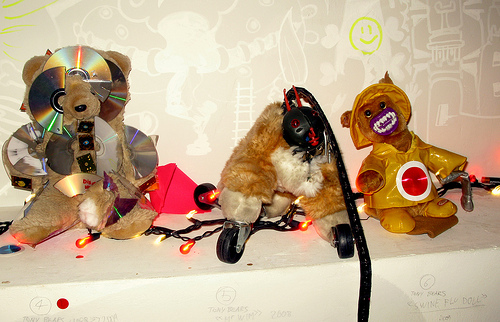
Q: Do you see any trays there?
A: No, there are no trays.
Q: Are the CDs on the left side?
A: Yes, the CDs are on the left of the image.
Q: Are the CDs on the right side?
A: No, the CDs are on the left of the image.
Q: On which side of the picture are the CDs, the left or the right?
A: The CDs are on the left of the image.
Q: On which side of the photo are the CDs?
A: The CDs are on the left of the image.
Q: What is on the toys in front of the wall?
A: The CDs are on the toys.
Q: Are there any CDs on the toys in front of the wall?
A: Yes, there are CDs on the toys.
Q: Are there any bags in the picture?
A: No, there are no bags.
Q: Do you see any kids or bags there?
A: No, there are no bags or kids.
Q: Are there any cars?
A: No, there are no cars.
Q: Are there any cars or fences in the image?
A: No, there are no cars or fences.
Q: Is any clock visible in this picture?
A: No, there are no clocks.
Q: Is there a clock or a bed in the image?
A: No, there are no clocks or beds.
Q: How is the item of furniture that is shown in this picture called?
A: The piece of furniture is a shelf.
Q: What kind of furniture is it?
A: The piece of furniture is a shelf.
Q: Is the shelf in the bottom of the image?
A: Yes, the shelf is in the bottom of the image.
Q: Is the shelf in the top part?
A: No, the shelf is in the bottom of the image.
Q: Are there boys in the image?
A: No, there are no boys.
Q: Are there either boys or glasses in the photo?
A: No, there are no boys or glasses.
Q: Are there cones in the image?
A: No, there are no cones.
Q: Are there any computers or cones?
A: No, there are no cones or computers.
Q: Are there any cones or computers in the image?
A: No, there are no cones or computers.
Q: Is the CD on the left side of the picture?
A: Yes, the CD is on the left of the image.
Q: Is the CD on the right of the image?
A: No, the CD is on the left of the image.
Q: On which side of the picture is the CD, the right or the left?
A: The CD is on the left of the image.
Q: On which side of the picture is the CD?
A: The CD is on the left of the image.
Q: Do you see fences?
A: No, there are no fences.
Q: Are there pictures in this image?
A: No, there are no pictures.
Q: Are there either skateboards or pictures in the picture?
A: No, there are no pictures or skateboards.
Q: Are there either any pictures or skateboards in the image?
A: No, there are no pictures or skateboards.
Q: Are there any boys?
A: No, there are no boys.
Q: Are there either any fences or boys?
A: No, there are no boys or fences.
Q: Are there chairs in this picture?
A: No, there are no chairs.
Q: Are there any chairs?
A: No, there are no chairs.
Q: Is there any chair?
A: No, there are no chairs.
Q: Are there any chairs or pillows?
A: No, there are no chairs or pillows.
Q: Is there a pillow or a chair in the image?
A: No, there are no chairs or pillows.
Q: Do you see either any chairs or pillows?
A: No, there are no chairs or pillows.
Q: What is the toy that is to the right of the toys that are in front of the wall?
A: The toy is a stuffed animal.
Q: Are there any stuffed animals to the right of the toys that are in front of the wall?
A: Yes, there is a stuffed animal to the right of the toys.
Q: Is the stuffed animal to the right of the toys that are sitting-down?
A: Yes, the stuffed animal is to the right of the toys.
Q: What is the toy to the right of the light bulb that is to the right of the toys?
A: The toy is a stuffed animal.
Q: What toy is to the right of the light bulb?
A: The toy is a stuffed animal.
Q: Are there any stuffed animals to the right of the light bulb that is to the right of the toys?
A: Yes, there is a stuffed animal to the right of the bulb.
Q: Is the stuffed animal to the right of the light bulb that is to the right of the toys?
A: Yes, the stuffed animal is to the right of the bulb.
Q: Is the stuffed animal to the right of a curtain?
A: No, the stuffed animal is to the right of the bulb.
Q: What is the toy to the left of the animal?
A: The toy is a stuffed animal.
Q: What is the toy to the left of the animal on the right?
A: The toy is a stuffed animal.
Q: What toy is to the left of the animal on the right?
A: The toy is a stuffed animal.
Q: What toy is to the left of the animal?
A: The toy is a stuffed animal.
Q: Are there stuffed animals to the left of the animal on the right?
A: Yes, there is a stuffed animal to the left of the animal.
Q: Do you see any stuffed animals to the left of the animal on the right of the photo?
A: Yes, there is a stuffed animal to the left of the animal.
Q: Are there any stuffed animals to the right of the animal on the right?
A: No, the stuffed animal is to the left of the animal.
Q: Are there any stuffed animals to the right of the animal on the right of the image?
A: No, the stuffed animal is to the left of the animal.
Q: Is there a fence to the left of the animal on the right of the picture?
A: No, there is a stuffed animal to the left of the animal.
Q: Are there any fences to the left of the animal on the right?
A: No, there is a stuffed animal to the left of the animal.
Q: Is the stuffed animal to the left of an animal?
A: Yes, the stuffed animal is to the left of an animal.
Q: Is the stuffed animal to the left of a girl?
A: No, the stuffed animal is to the left of an animal.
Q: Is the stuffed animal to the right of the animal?
A: No, the stuffed animal is to the left of the animal.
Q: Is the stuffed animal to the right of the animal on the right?
A: No, the stuffed animal is to the left of the animal.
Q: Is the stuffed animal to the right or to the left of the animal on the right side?
A: The stuffed animal is to the left of the animal.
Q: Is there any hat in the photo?
A: Yes, there is a hat.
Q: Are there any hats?
A: Yes, there is a hat.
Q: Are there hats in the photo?
A: Yes, there is a hat.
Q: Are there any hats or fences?
A: Yes, there is a hat.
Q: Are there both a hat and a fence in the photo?
A: No, there is a hat but no fences.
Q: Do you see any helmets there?
A: No, there are no helmets.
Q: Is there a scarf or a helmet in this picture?
A: No, there are no helmets or scarves.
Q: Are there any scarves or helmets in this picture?
A: No, there are no helmets or scarves.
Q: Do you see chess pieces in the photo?
A: No, there are no chess pieces.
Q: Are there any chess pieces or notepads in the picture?
A: No, there are no chess pieces or notepads.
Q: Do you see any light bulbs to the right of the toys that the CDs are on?
A: Yes, there is a light bulb to the right of the toys.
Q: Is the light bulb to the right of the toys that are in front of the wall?
A: Yes, the light bulb is to the right of the toys.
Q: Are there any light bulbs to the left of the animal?
A: Yes, there is a light bulb to the left of the animal.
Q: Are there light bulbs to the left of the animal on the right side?
A: Yes, there is a light bulb to the left of the animal.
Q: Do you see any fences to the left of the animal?
A: No, there is a light bulb to the left of the animal.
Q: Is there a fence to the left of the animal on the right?
A: No, there is a light bulb to the left of the animal.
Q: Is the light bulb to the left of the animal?
A: Yes, the light bulb is to the left of the animal.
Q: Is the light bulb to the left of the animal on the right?
A: Yes, the light bulb is to the left of the animal.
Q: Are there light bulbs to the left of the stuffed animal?
A: Yes, there is a light bulb to the left of the stuffed animal.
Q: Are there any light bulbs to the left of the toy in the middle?
A: Yes, there is a light bulb to the left of the stuffed animal.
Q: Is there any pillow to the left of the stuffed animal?
A: No, there is a light bulb to the left of the stuffed animal.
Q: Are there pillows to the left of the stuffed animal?
A: No, there is a light bulb to the left of the stuffed animal.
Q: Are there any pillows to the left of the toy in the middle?
A: No, there is a light bulb to the left of the stuffed animal.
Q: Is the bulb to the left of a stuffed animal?
A: Yes, the bulb is to the left of a stuffed animal.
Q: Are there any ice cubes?
A: No, there are no ice cubes.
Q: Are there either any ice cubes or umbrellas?
A: No, there are no ice cubes or umbrellas.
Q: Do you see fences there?
A: No, there are no fences.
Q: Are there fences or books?
A: No, there are no fences or books.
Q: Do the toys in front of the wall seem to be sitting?
A: Yes, the toys are sitting.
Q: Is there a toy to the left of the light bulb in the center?
A: Yes, there are toys to the left of the light bulb.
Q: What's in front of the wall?
A: The toys are in front of the wall.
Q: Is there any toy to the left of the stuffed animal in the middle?
A: Yes, there are toys to the left of the stuffed animal.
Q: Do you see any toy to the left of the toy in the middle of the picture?
A: Yes, there are toys to the left of the stuffed animal.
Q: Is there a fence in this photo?
A: No, there are no fences.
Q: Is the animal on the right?
A: Yes, the animal is on the right of the image.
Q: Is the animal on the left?
A: No, the animal is on the right of the image.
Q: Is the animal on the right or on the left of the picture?
A: The animal is on the right of the image.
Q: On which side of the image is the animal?
A: The animal is on the right of the image.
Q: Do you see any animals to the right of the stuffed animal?
A: Yes, there is an animal to the right of the stuffed animal.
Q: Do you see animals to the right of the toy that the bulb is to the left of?
A: Yes, there is an animal to the right of the stuffed animal.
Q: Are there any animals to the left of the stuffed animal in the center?
A: No, the animal is to the right of the stuffed animal.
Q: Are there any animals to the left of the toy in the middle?
A: No, the animal is to the right of the stuffed animal.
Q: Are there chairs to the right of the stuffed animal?
A: No, there is an animal to the right of the stuffed animal.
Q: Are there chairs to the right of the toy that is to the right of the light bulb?
A: No, there is an animal to the right of the stuffed animal.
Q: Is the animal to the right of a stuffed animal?
A: Yes, the animal is to the right of a stuffed animal.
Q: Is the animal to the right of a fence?
A: No, the animal is to the right of a stuffed animal.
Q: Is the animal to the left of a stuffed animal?
A: No, the animal is to the right of a stuffed animal.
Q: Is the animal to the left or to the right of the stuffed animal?
A: The animal is to the right of the stuffed animal.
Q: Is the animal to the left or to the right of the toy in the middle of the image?
A: The animal is to the right of the stuffed animal.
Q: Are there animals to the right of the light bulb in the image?
A: Yes, there is an animal to the right of the light bulb.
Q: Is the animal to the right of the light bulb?
A: Yes, the animal is to the right of the light bulb.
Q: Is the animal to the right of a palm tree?
A: No, the animal is to the right of the light bulb.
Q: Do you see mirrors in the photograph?
A: No, there are no mirrors.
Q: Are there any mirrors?
A: No, there are no mirrors.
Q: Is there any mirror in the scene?
A: No, there are no mirrors.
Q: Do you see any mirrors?
A: No, there are no mirrors.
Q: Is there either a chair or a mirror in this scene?
A: No, there are no mirrors or chairs.